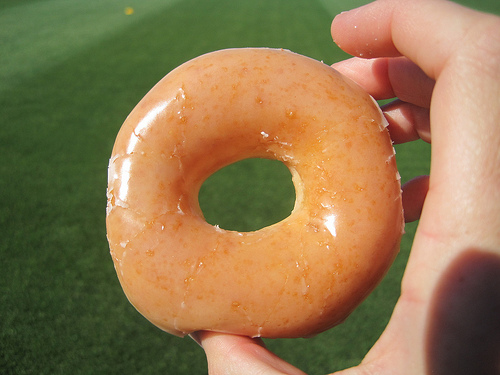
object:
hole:
[198, 155, 295, 232]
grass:
[0, 0, 105, 369]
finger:
[196, 331, 304, 374]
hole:
[196, 148, 300, 232]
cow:
[105, 47, 407, 338]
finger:
[330, 0, 499, 81]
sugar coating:
[310, 186, 374, 257]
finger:
[378, 99, 430, 146]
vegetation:
[0, 1, 500, 375]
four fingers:
[330, 0, 467, 223]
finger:
[327, 55, 432, 110]